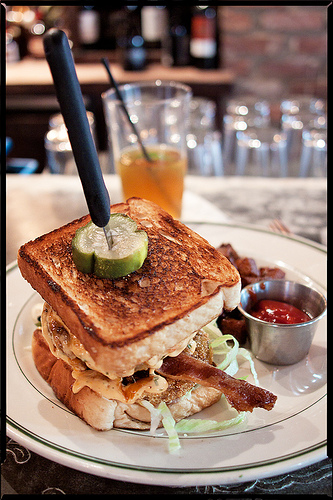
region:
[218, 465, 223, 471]
the plate has green lining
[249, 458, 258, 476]
the plate has green lining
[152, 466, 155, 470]
the plate has green lining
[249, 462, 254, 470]
the plate has green lining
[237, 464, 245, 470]
the plate has green lining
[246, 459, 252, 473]
the plate has green lining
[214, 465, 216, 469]
the plate has green lining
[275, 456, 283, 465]
the plate has green lining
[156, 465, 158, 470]
the plate has green lining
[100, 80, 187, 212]
clear glass half full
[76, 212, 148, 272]
thick sliced picle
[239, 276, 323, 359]
the metal cup of ketchup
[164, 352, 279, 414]
the crispy bacon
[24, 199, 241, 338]
the top toasted bread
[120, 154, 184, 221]
the liquid in the cup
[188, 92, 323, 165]
the clear glassed lined up in the back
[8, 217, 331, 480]
the round plate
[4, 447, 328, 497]
the green trim on the edge of the plate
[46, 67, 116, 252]
the knife with the black handle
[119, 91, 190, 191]
this is a glass of juice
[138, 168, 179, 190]
the juice is yellow in color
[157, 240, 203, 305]
this is a toast bread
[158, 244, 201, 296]
the bread is brown in color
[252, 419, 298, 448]
this is a plate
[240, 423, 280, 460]
the plate is white in color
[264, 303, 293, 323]
this is a tomato paste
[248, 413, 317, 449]
the plate is of glass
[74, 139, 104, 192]
the handle is black in color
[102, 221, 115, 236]
this is a knife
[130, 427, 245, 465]
the plate is white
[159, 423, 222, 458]
the plate is white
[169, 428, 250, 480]
the plate is white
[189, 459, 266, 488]
the plate is white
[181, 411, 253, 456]
the plate is white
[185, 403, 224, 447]
the plate is white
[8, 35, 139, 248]
the knife handle is black